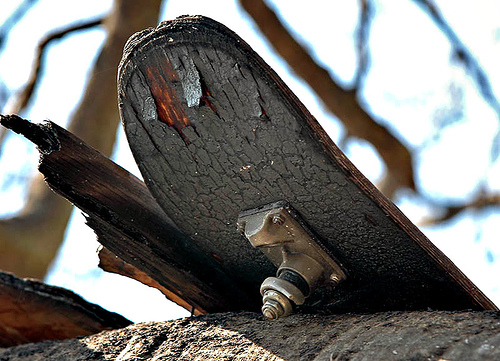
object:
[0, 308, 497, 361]
wood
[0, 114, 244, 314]
wood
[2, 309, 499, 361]
material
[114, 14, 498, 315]
wood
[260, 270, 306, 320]
screw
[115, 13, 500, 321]
board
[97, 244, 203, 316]
bark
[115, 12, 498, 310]
board's paint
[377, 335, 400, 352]
piece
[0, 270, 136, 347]
wood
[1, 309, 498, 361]
bark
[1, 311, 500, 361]
log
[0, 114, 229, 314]
log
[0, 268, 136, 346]
bark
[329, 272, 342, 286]
bolt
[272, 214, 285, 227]
silver bolt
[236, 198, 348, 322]
truck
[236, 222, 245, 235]
bolt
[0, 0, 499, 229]
tree branches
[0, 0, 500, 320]
sky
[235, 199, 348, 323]
metal part